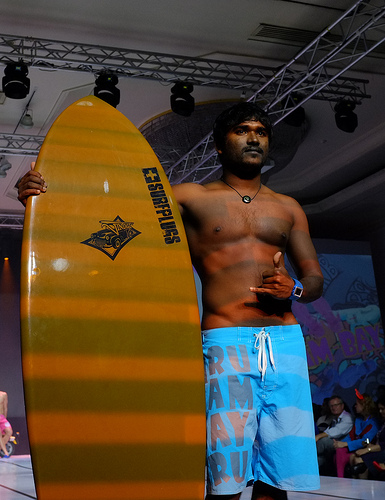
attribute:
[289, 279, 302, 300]
watch — blue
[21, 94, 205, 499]
surfboard — yellow, large, orange, wooden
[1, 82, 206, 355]
surfboard — yellow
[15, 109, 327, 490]
person — standing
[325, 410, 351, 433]
shirt — white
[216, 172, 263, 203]
necklace — black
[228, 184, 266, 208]
necklace — simple, black, silver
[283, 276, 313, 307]
watch — blue, plastic, smart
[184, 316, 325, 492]
shorts — blue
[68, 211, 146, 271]
logo — black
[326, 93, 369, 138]
light — black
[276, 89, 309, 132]
light — black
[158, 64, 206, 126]
light — black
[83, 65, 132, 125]
light — black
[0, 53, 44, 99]
light — black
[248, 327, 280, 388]
string — white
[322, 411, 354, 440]
shirt — white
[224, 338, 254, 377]
letter — gray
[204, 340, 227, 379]
letter — gray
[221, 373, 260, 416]
letter — gray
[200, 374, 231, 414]
letter — gray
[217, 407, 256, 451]
letter — gray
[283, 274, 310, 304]
watch — smart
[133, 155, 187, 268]
writing — black